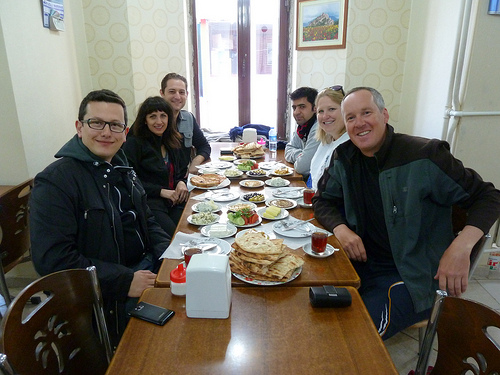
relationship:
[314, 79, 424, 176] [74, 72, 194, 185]
person sitting next to a person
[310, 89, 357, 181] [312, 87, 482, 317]
person sitting next to a person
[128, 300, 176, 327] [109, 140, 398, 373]
cell phone on a wooden table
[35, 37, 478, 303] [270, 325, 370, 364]
people sitting at table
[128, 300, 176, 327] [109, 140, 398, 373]
cell phone on a table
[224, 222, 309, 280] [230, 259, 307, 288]
bread on a plate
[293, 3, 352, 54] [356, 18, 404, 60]
picture on a wall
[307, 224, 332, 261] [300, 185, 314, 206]
beverage in a glass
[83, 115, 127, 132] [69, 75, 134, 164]
black glasses on face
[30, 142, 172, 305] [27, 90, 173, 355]
jacket on a people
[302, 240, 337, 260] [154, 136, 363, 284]
small plate on a table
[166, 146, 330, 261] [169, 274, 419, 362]
plates on a table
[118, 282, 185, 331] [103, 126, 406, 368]
cell phone on table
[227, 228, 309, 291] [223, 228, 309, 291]
plate of pita